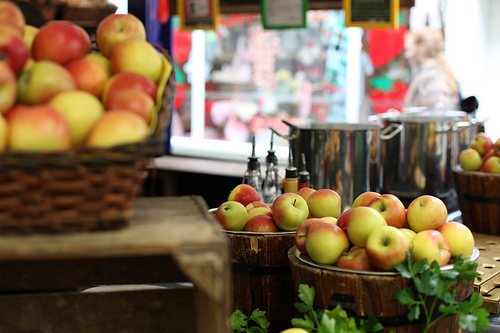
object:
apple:
[216, 201, 250, 232]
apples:
[272, 192, 310, 231]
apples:
[84, 110, 149, 149]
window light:
[167, 19, 358, 161]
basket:
[0, 152, 156, 234]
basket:
[288, 246, 480, 332]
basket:
[227, 233, 300, 332]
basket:
[452, 164, 499, 234]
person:
[402, 27, 465, 122]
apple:
[307, 223, 350, 265]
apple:
[365, 227, 407, 272]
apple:
[338, 246, 371, 270]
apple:
[336, 206, 389, 247]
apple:
[407, 195, 448, 234]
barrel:
[287, 246, 479, 332]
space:
[0, 285, 72, 295]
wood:
[5, 235, 229, 279]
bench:
[1, 195, 231, 330]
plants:
[391, 250, 493, 333]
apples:
[459, 148, 483, 171]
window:
[205, 11, 347, 145]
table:
[448, 223, 498, 320]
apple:
[412, 229, 451, 267]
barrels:
[227, 231, 299, 332]